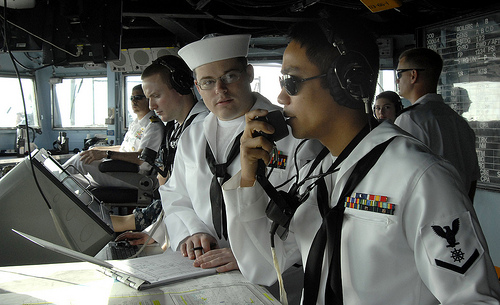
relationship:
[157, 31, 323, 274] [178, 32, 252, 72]
man wearing hat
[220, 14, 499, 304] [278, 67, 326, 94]
man wearing sunglasses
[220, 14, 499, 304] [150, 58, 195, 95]
man wearing headphones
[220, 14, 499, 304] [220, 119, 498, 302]
man wearing shirt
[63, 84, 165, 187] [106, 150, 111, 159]
man wearing watch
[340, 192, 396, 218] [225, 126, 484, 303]
stripes on uniform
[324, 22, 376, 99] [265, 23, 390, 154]
headphones on head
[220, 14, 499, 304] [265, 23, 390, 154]
man has head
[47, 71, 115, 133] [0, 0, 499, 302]
window in boat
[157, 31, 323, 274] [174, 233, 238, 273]
man has hands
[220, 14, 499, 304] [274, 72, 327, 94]
man wearing sunglasses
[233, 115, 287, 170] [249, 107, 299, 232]
hand holding speaker phone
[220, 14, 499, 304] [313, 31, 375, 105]
man wearing headphones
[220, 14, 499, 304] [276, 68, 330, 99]
man wearing sunglasses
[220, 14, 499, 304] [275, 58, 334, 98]
man wearing sunglasses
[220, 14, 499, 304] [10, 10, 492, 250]
man on boat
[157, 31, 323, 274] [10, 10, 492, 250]
man on boat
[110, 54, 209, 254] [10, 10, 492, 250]
man on boat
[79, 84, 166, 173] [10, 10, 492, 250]
man on boat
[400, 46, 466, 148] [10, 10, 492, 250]
man on boat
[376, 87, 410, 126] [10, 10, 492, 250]
man on boat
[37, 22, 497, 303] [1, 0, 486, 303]
people on boat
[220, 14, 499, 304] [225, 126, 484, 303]
man in uniform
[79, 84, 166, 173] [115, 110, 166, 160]
man in uniform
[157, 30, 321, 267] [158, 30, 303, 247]
man in uniform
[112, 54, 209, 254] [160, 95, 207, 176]
man in uniform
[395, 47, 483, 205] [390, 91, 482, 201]
man in uniform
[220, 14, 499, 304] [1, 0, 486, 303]
man on boat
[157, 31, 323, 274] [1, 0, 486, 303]
man on boat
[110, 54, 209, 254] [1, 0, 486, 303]
man on boat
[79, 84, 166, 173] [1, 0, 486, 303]
man on boat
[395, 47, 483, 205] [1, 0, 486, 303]
man on boat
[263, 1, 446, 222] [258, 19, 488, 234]
man wearing sunglasses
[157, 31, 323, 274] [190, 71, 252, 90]
man wearing glasses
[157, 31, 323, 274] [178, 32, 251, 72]
man with hat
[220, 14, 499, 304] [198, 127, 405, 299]
man with ties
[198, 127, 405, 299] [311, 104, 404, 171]
ties on neck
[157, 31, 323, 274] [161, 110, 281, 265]
man on uniform